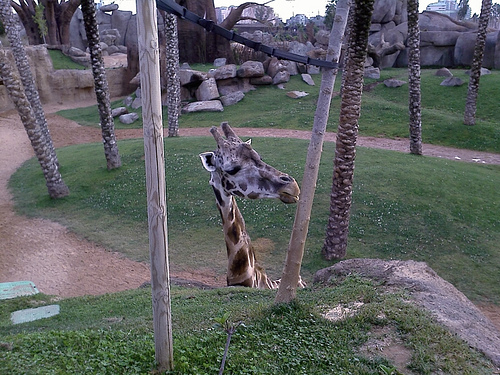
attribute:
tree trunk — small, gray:
[279, 150, 318, 286]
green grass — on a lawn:
[382, 158, 482, 249]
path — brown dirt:
[1, 100, 126, 309]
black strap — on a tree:
[157, 0, 338, 79]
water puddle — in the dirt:
[452, 150, 484, 168]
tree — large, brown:
[15, 0, 86, 42]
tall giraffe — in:
[194, 118, 302, 285]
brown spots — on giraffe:
[231, 230, 252, 281]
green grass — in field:
[377, 166, 447, 246]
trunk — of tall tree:
[323, 42, 360, 268]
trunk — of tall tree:
[84, 41, 129, 168]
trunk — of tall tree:
[157, 35, 187, 142]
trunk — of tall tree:
[82, 30, 122, 170]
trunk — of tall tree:
[157, 29, 181, 138]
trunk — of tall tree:
[75, 2, 124, 170]